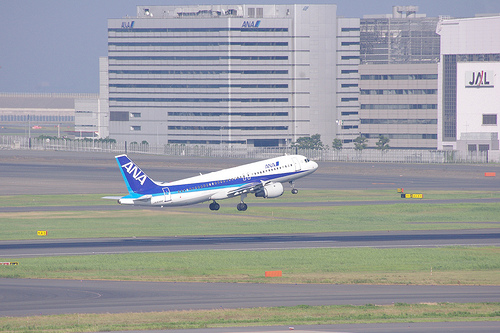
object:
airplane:
[103, 153, 319, 210]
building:
[99, 5, 338, 143]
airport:
[0, 149, 499, 333]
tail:
[114, 154, 154, 194]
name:
[242, 20, 261, 27]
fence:
[0, 133, 489, 166]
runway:
[0, 232, 499, 257]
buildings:
[335, 5, 439, 149]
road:
[1, 124, 75, 132]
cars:
[32, 125, 41, 129]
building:
[74, 99, 110, 132]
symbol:
[266, 271, 283, 277]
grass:
[1, 247, 499, 282]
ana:
[121, 162, 147, 185]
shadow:
[0, 162, 121, 171]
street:
[1, 149, 500, 195]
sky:
[1, 0, 500, 85]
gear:
[209, 203, 220, 210]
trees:
[291, 133, 321, 150]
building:
[437, 15, 499, 150]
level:
[105, 36, 293, 38]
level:
[108, 70, 290, 75]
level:
[108, 56, 290, 61]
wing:
[101, 197, 120, 199]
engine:
[255, 180, 284, 198]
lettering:
[469, 70, 489, 85]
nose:
[311, 161, 318, 173]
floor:
[108, 106, 291, 107]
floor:
[108, 50, 291, 52]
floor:
[110, 92, 289, 94]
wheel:
[237, 203, 247, 212]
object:
[412, 194, 423, 199]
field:
[0, 189, 499, 329]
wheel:
[291, 189, 298, 194]